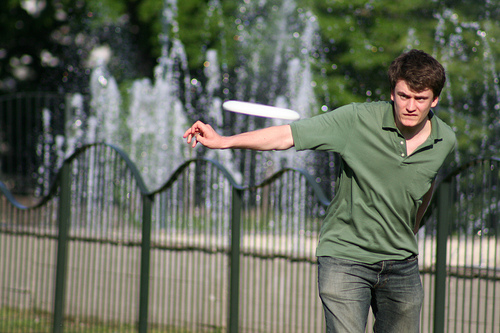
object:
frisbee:
[208, 93, 310, 125]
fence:
[2, 128, 499, 332]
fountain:
[25, 0, 499, 243]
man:
[187, 42, 463, 331]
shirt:
[275, 100, 455, 264]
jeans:
[311, 254, 428, 332]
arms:
[180, 101, 379, 156]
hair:
[384, 45, 449, 100]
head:
[383, 49, 446, 128]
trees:
[0, 2, 499, 225]